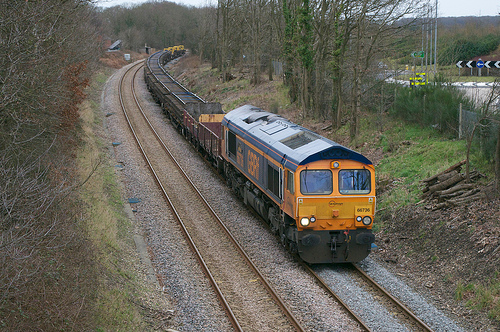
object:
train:
[144, 44, 374, 263]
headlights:
[300, 217, 310, 227]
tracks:
[299, 264, 378, 332]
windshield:
[338, 169, 372, 195]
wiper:
[304, 167, 309, 193]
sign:
[413, 51, 424, 58]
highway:
[376, 61, 500, 114]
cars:
[160, 93, 228, 172]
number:
[356, 207, 370, 212]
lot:
[386, 76, 500, 88]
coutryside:
[378, 118, 472, 202]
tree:
[279, 0, 438, 153]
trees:
[200, 0, 278, 86]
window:
[299, 169, 333, 196]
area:
[460, 87, 500, 115]